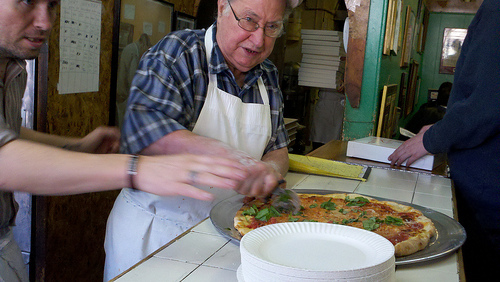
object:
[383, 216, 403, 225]
leaf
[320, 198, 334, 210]
leaf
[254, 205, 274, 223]
leaf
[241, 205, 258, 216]
leaf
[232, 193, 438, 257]
pizza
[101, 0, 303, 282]
person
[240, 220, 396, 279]
plates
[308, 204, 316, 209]
vegetable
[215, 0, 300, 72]
head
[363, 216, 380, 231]
leaf